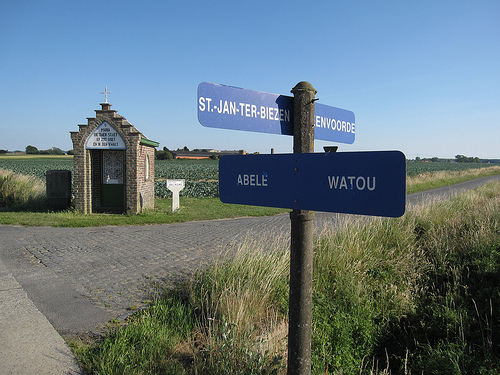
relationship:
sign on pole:
[219, 150, 405, 218] [290, 79, 318, 374]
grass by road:
[66, 176, 500, 374] [0, 175, 499, 374]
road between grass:
[0, 175, 499, 374] [66, 176, 500, 374]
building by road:
[70, 103, 160, 214] [0, 175, 499, 374]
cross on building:
[101, 86, 114, 105] [70, 103, 160, 214]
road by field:
[0, 175, 499, 374] [0, 154, 497, 227]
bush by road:
[1, 167, 47, 213] [0, 175, 499, 374]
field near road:
[0, 154, 497, 227] [0, 175, 499, 374]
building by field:
[70, 103, 160, 214] [0, 154, 497, 227]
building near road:
[70, 103, 160, 214] [0, 175, 499, 374]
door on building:
[100, 149, 127, 207] [70, 103, 160, 214]